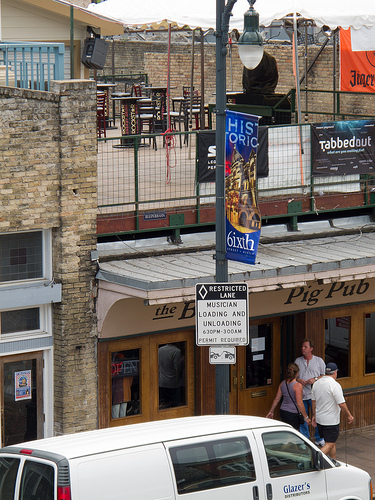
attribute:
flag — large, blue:
[221, 107, 264, 265]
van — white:
[9, 412, 365, 498]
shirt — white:
[308, 373, 343, 426]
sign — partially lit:
[109, 346, 141, 419]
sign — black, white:
[195, 282, 249, 345]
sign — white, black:
[207, 347, 235, 364]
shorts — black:
[314, 422, 344, 443]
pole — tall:
[214, 1, 250, 417]